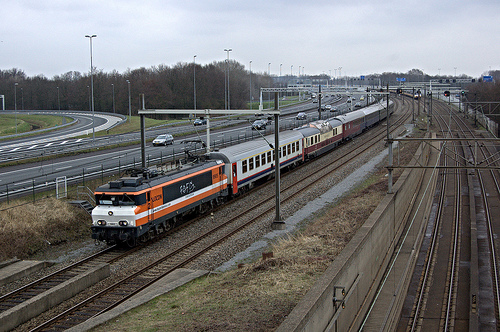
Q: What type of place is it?
A: It is a road.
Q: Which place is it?
A: It is a road.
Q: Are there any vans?
A: No, there are no vans.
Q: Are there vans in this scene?
A: No, there are no vans.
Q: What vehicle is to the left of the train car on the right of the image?
A: The vehicle is a car.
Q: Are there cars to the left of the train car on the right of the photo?
A: Yes, there is a car to the left of the train car.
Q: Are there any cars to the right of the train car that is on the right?
A: No, the car is to the left of the train car.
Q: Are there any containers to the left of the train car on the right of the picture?
A: No, there is a car to the left of the train car.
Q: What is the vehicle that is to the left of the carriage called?
A: The vehicle is a car.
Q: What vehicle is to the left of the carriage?
A: The vehicle is a car.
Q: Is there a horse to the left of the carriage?
A: No, there is a car to the left of the carriage.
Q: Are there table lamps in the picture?
A: No, there are no table lamps.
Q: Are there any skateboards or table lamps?
A: No, there are no table lamps or skateboards.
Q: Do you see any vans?
A: No, there are no vans.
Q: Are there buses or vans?
A: No, there are no vans or buses.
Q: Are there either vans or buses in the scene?
A: No, there are no vans or buses.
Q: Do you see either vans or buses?
A: No, there are no vans or buses.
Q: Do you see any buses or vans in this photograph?
A: No, there are no vans or buses.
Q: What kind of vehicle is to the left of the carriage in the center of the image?
A: The vehicles are cars.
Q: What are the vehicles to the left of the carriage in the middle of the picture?
A: The vehicles are cars.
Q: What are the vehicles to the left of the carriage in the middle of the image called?
A: The vehicles are cars.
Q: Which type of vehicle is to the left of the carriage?
A: The vehicles are cars.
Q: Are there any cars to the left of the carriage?
A: Yes, there are cars to the left of the carriage.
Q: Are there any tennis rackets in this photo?
A: No, there are no tennis rackets.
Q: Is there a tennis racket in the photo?
A: No, there are no rackets.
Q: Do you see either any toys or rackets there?
A: No, there are no rackets or toys.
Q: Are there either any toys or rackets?
A: No, there are no rackets or toys.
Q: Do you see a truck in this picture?
A: No, there are no trucks.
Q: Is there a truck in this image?
A: No, there are no trucks.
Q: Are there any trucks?
A: No, there are no trucks.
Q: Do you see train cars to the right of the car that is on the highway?
A: Yes, there is a train car to the right of the car.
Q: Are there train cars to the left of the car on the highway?
A: No, the train car is to the right of the car.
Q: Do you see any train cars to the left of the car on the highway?
A: No, the train car is to the right of the car.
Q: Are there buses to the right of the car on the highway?
A: No, there is a train car to the right of the car.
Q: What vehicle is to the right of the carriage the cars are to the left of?
A: The vehicle is a train car.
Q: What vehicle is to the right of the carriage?
A: The vehicle is a train car.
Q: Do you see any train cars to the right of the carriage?
A: Yes, there is a train car to the right of the carriage.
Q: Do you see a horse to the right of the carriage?
A: No, there is a train car to the right of the carriage.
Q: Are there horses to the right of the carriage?
A: No, there is a train car to the right of the carriage.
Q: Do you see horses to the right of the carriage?
A: No, there is a train car to the right of the carriage.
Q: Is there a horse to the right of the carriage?
A: No, there is a train car to the right of the carriage.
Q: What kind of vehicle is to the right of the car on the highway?
A: The vehicle is a train car.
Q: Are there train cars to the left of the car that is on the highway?
A: No, the train car is to the right of the car.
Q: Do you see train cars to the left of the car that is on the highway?
A: No, the train car is to the right of the car.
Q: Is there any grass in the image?
A: Yes, there is grass.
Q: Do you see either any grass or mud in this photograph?
A: Yes, there is grass.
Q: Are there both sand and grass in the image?
A: No, there is grass but no sand.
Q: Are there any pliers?
A: No, there are no pliers.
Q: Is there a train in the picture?
A: Yes, there is a train.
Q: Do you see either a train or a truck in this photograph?
A: Yes, there is a train.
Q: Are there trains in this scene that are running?
A: Yes, there is a train that is running.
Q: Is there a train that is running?
A: Yes, there is a train that is running.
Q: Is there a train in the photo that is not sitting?
A: Yes, there is a train that is running.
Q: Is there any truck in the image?
A: No, there are no trucks.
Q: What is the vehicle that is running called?
A: The vehicle is a train.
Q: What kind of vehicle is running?
A: The vehicle is a train.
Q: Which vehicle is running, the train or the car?
A: The train is running.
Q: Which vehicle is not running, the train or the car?
A: The car is not running.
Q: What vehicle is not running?
A: The vehicle is a car.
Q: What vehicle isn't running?
A: The vehicle is a car.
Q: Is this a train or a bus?
A: This is a train.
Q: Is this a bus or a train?
A: This is a train.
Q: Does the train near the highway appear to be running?
A: Yes, the train is running.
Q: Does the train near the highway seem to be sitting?
A: No, the train is running.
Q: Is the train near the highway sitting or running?
A: The train is running.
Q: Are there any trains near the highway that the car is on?
A: Yes, there is a train near the highway.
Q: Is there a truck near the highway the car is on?
A: No, there is a train near the highway.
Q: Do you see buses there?
A: No, there are no buses.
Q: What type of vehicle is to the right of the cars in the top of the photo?
A: The vehicle is a train car.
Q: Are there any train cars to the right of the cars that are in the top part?
A: Yes, there is a train car to the right of the cars.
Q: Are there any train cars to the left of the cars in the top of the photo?
A: No, the train car is to the right of the cars.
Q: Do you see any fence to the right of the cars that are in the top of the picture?
A: No, there is a train car to the right of the cars.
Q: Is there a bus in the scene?
A: No, there are no buses.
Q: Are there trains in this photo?
A: Yes, there is a train.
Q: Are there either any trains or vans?
A: Yes, there is a train.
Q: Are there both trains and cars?
A: Yes, there are both a train and a car.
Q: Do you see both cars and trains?
A: Yes, there are both a train and a car.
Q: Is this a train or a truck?
A: This is a train.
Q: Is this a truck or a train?
A: This is a train.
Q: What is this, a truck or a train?
A: This is a train.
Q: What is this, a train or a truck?
A: This is a train.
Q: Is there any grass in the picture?
A: Yes, there is grass.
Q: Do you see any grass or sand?
A: Yes, there is grass.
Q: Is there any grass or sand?
A: Yes, there is grass.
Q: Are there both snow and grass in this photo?
A: No, there is grass but no snow.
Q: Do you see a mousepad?
A: No, there are no mouse pads.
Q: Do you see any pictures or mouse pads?
A: No, there are no mouse pads or pictures.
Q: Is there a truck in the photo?
A: No, there are no trucks.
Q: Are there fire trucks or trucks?
A: No, there are no trucks or fire trucks.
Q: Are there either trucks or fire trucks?
A: No, there are no trucks or fire trucks.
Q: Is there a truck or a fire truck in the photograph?
A: No, there are no trucks or fire trucks.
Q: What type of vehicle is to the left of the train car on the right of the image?
A: The vehicle is a car.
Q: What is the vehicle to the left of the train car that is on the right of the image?
A: The vehicle is a car.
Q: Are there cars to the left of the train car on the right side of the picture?
A: Yes, there is a car to the left of the train car.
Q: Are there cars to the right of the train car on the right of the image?
A: No, the car is to the left of the train car.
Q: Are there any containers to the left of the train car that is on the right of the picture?
A: No, there is a car to the left of the train car.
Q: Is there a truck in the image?
A: No, there are no trucks.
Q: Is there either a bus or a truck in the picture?
A: No, there are no trucks or buses.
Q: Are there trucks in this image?
A: No, there are no trucks.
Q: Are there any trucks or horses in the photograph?
A: No, there are no trucks or horses.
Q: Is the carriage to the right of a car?
A: Yes, the carriage is to the right of a car.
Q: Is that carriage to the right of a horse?
A: No, the carriage is to the right of a car.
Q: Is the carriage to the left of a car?
A: No, the carriage is to the right of a car.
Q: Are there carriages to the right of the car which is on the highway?
A: Yes, there is a carriage to the right of the car.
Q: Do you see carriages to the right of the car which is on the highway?
A: Yes, there is a carriage to the right of the car.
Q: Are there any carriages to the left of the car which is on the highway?
A: No, the carriage is to the right of the car.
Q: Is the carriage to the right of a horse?
A: No, the carriage is to the right of a car.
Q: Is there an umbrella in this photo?
A: No, there are no umbrellas.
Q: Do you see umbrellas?
A: No, there are no umbrellas.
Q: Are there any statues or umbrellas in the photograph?
A: No, there are no umbrellas or statues.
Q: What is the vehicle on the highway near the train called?
A: The vehicle is a car.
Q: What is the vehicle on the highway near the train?
A: The vehicle is a car.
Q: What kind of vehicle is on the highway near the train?
A: The vehicle is a car.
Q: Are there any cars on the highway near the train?
A: Yes, there is a car on the highway.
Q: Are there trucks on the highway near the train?
A: No, there is a car on the highway.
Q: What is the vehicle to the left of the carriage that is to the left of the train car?
A: The vehicle is a car.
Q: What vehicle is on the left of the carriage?
A: The vehicle is a car.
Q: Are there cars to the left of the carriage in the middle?
A: Yes, there is a car to the left of the carriage.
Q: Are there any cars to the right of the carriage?
A: No, the car is to the left of the carriage.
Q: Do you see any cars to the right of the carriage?
A: No, the car is to the left of the carriage.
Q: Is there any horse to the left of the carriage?
A: No, there is a car to the left of the carriage.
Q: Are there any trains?
A: Yes, there is a train.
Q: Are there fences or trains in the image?
A: Yes, there is a train.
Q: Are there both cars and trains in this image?
A: Yes, there are both a train and a car.